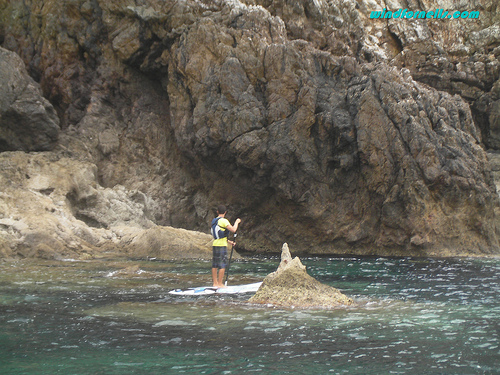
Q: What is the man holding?
A: A paddle.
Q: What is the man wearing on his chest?
A: Life Jacket.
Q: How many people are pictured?
A: One.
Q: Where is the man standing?
A: On a paddleboard.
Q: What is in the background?
A: Rock cliffs.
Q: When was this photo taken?
A: During the daytime.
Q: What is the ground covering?
A: Water.